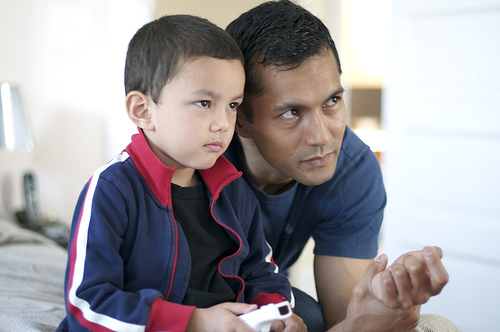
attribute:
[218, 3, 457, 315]
man — groomed, short, neat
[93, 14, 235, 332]
boy — sitting, frowning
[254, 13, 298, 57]
hair — dark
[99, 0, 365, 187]
man and boy — staring